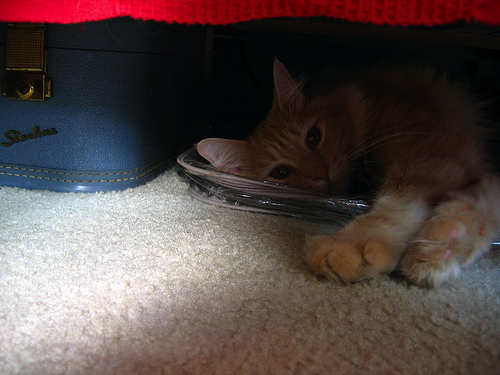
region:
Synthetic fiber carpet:
[40, 217, 320, 355]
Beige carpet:
[34, 170, 319, 340]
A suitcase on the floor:
[7, 19, 296, 252]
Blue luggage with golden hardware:
[5, 27, 290, 243]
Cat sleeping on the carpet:
[184, 40, 499, 314]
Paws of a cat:
[250, 180, 498, 322]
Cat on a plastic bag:
[173, 41, 495, 347]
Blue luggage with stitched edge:
[3, 23, 237, 273]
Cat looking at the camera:
[155, 52, 499, 292]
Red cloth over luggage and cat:
[1, 1, 489, 141]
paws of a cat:
[347, 247, 377, 277]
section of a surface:
[186, 278, 225, 303]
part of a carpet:
[93, 253, 145, 310]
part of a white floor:
[82, 248, 129, 262]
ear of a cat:
[236, 136, 244, 146]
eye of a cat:
[276, 163, 296, 174]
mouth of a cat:
[329, 172, 340, 190]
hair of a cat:
[362, 144, 384, 156]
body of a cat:
[431, 125, 455, 142]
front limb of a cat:
[414, 229, 425, 236]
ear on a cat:
[252, 34, 312, 127]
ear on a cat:
[185, 130, 265, 179]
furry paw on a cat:
[295, 210, 415, 297]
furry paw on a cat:
[392, 203, 483, 290]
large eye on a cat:
[298, 107, 328, 157]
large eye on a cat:
[252, 153, 306, 190]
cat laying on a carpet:
[140, 28, 499, 327]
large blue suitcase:
[0, 6, 277, 208]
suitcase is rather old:
[0, 1, 242, 211]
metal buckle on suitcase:
[0, 2, 72, 114]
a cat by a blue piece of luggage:
[195, 57, 498, 285]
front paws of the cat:
[303, 215, 494, 288]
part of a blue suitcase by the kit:
[1, 22, 171, 194]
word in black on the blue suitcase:
[1, 122, 60, 149]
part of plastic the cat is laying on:
[192, 171, 264, 208]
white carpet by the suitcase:
[88, 197, 187, 251]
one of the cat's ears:
[193, 136, 253, 175]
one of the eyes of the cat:
[298, 111, 330, 154]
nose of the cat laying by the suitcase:
[312, 162, 337, 185]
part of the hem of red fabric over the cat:
[182, 2, 271, 25]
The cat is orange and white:
[193, 54, 498, 285]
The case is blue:
[0, 18, 211, 201]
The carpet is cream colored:
[1, 155, 491, 374]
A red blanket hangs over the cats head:
[1, 1, 498, 27]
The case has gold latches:
[1, 21, 61, 103]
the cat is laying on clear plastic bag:
[176, 128, 498, 242]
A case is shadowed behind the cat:
[205, 21, 499, 142]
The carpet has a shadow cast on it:
[3, 189, 498, 374]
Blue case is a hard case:
[1, 3, 202, 195]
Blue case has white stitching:
[1, 145, 191, 187]